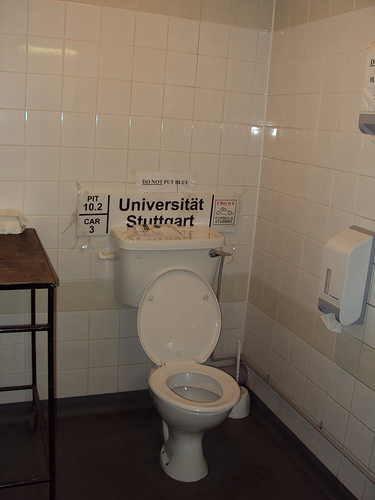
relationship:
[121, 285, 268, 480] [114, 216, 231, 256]
toilet has sink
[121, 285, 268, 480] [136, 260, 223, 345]
toilet has lid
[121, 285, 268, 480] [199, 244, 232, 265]
toilet has hadle